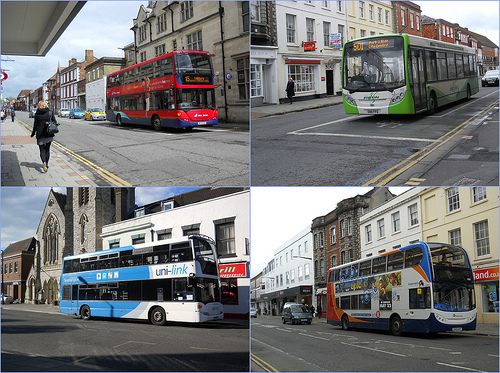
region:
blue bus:
[25, 232, 215, 347]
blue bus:
[40, 190, 230, 320]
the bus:
[338, 228, 438, 370]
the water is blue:
[338, 278, 387, 370]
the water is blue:
[375, 253, 416, 363]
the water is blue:
[344, 242, 398, 344]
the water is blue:
[341, 205, 422, 328]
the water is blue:
[371, 183, 422, 362]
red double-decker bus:
[94, 56, 226, 139]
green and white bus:
[353, 38, 484, 117]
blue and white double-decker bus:
[15, 225, 218, 350]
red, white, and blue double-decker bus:
[319, 264, 496, 353]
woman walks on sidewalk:
[32, 103, 79, 175]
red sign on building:
[292, 35, 319, 60]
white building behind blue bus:
[89, 223, 271, 330]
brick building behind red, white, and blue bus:
[307, 218, 353, 274]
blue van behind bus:
[276, 304, 316, 325]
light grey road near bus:
[81, 118, 210, 174]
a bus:
[346, 261, 429, 352]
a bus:
[351, 217, 430, 329]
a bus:
[376, 257, 412, 355]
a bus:
[338, 245, 400, 367]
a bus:
[354, 293, 432, 368]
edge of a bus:
[417, 274, 444, 317]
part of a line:
[256, 326, 272, 350]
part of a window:
[201, 280, 225, 291]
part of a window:
[467, 227, 486, 262]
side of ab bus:
[350, 253, 425, 317]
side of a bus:
[101, 288, 163, 332]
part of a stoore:
[223, 278, 238, 298]